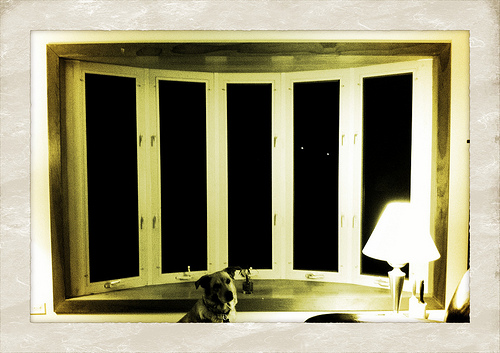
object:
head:
[194, 267, 243, 308]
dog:
[176, 265, 243, 326]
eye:
[224, 276, 232, 283]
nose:
[223, 290, 235, 297]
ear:
[194, 276, 208, 288]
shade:
[362, 74, 409, 276]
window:
[224, 82, 277, 276]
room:
[0, 0, 498, 353]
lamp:
[361, 199, 439, 313]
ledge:
[54, 277, 426, 310]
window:
[153, 80, 210, 272]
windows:
[78, 65, 139, 286]